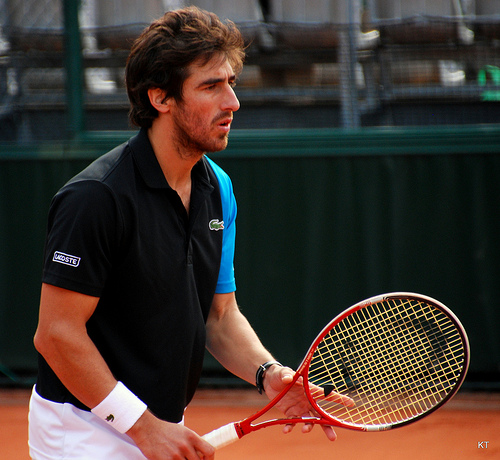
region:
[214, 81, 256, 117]
nose of the player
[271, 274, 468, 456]
racket in player's hand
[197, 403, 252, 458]
handle of the racket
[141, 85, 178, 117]
ear of the player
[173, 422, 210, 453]
hand of the player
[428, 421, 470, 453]
ground below the player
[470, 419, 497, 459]
letters in bottom right corner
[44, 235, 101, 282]
word on the shirt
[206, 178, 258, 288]
blue sleeve on shirt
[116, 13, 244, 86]
hair on man's head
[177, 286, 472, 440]
a tennis racket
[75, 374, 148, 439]
a wristband worn by a tennis player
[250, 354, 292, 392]
a wristwatch worn by a young man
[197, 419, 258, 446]
the white handle of a tennis racket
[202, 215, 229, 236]
a green aligator logo on a shirt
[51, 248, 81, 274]
the Lacoste logo on the sleeve of a shirt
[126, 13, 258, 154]
the head of a young man playing tennis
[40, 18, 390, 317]
a tennis player playing tennis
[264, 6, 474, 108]
spectator seats at a tennis court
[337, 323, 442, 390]
the strings of a tennis racket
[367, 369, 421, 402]
Wires on the racket.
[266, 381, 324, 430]
The racket is red.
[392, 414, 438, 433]
Part of the racket is black.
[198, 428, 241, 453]
The handle is white.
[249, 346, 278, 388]
The watch is black.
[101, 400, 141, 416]
The sweatband is white.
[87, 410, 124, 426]
Logo on the sweatband.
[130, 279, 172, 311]
The shirt is black.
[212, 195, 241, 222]
Blue on the shirt.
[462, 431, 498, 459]
"KT" in the corner.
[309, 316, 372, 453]
a red tennis racket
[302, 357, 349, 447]
a red tennis racket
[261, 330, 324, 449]
a red tennis racket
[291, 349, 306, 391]
a red tennis racket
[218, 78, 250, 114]
nose of the man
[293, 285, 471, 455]
racket in man's hand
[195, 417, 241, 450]
handle of the racket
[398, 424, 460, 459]
red ground under man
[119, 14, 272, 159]
head of the man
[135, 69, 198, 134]
ear of the man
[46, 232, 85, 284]
writing on the shirt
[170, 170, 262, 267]
black and blue shirt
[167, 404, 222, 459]
hand on the racket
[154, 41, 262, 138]
man with a beard